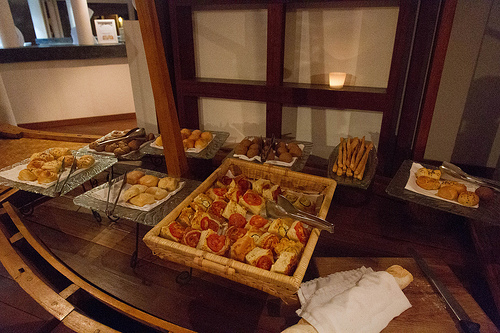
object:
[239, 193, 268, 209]
rolls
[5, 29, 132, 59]
counter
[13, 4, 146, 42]
front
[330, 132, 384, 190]
tray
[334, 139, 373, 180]
snacks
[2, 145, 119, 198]
tray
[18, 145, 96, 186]
rolls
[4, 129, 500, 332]
table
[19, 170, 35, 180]
bread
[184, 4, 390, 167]
window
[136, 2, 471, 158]
wall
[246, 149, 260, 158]
brown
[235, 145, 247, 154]
bread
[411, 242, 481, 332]
knife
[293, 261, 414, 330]
loaf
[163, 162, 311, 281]
sandwiches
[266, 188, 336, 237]
tong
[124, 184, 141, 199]
baguette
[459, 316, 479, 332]
handle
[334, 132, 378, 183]
bread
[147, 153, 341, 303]
tray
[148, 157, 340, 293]
wicker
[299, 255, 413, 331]
towel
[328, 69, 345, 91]
candle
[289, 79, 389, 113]
shelf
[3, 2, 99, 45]
column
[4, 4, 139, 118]
background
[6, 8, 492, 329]
photo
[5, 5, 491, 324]
indoors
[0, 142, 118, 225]
container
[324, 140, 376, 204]
basket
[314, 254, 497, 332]
board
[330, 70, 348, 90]
holder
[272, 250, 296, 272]
tomato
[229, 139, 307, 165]
plate